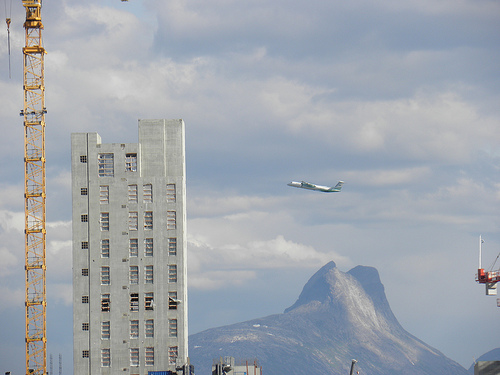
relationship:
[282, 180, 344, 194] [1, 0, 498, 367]
airplane flying in sky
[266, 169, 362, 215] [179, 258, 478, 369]
airplane above mountain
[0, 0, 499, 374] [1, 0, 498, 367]
cloud in sky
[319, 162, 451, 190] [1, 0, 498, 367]
cloud in sky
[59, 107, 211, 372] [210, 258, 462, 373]
building next to mountain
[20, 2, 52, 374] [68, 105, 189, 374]
equipment next to building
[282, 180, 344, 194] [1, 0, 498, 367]
airplane in sky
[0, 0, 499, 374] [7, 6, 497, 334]
cloud in sky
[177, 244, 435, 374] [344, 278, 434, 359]
mountain with slope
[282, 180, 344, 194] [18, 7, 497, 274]
airplane amongst clouds